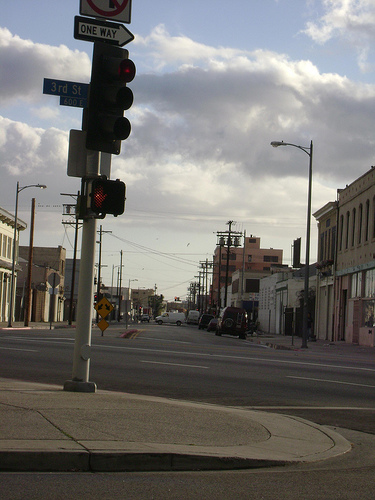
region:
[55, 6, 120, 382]
traffic signal on metal pole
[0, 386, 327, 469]
concrete curb on street corner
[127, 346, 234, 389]
white lines painted on road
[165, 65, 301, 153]
white clouds overhead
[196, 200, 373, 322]
buildings on right side of road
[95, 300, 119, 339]
two diamond shaped yellow signs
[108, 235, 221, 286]
electric lines over road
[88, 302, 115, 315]
black arrows on sign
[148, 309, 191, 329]
the van is white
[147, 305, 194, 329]
the van is white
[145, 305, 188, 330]
the van is white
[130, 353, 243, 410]
the street is paved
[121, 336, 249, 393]
the street is paved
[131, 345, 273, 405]
the street is paved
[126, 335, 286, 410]
the street is paved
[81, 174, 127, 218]
red stop hand signal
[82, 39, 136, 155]
red lit light on a traffic signal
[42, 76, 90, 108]
two blue and white street signs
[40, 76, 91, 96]
street sign reading 3rd St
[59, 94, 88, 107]
street sign reading 600 E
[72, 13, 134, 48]
black and white street sign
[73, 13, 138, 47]
street sign reading one way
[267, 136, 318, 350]
tall gray street light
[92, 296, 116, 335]
arrows on a yellow traffic sign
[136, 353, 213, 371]
white line on a gray ground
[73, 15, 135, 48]
black and white 'one way' sign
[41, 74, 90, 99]
blue and white '3rd St' sign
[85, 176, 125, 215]
pedestrian crossing light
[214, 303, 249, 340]
dark van parked on the street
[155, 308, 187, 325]
white van driving across street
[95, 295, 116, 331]
yellow diamond shaped signs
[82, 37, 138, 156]
stoplight light up red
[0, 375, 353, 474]
sidewalk below stoplight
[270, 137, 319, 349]
street light behind parked van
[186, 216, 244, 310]
series of telephone poles along street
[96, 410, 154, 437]
the sidewalk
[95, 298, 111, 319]
a yellow sign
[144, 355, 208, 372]
a white line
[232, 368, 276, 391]
the street is black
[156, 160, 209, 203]
the white cloud in the sky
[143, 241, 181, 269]
power lines in the sky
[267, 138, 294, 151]
a street light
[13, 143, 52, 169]
the white cloud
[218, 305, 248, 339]
a parked van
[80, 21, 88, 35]
black letter on sign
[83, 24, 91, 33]
black letter on sign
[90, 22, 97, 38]
black letter on sign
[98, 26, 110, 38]
black letter on sign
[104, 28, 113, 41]
black letter on sign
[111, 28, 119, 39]
black letter on sign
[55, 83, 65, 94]
white letter on sign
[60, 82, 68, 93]
white letter on sign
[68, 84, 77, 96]
white letter on sign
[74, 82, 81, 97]
white letter on sign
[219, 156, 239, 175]
a white fluffy cloud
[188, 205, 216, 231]
a white fluffy cloud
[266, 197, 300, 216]
a white fluffy cloud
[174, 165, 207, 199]
a white fluffy cloud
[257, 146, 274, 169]
a white fluffy cloud